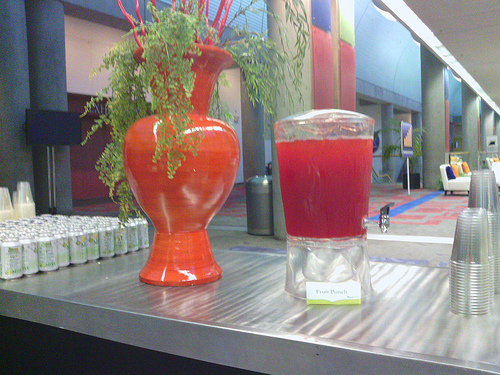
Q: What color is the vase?
A: Orange.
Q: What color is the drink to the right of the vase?
A: Red.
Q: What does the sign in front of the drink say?
A: Fruit punch.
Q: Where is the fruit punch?
A: In a dispenser.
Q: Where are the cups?
A: To the right of the fruit punch.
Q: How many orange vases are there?
A: One.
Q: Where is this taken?
A: A lobby.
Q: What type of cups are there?
A: Plastic.